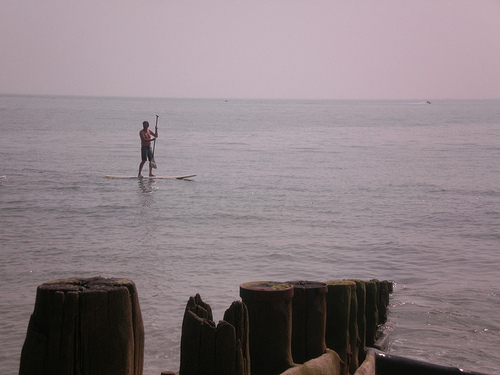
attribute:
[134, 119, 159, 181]
man — alone, standing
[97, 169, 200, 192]
surfboard — present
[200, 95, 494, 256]
water — calm, grey, present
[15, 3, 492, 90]
sky — grey, cloudy, present, foggy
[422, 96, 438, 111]
seabird — far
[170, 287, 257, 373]
post — broken, wooden, old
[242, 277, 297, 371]
post — old, wooden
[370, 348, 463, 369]
trunk — present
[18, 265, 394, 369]
posts — rounded, present, wood